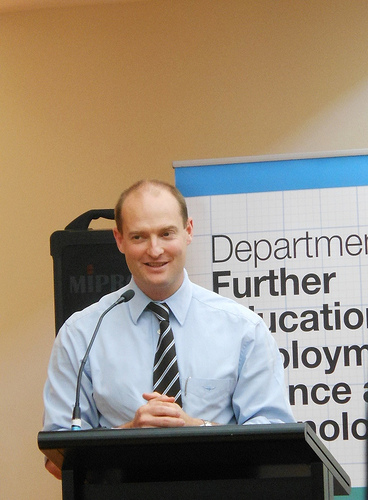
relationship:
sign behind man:
[169, 146, 363, 489] [26, 165, 304, 416]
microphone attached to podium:
[70, 289, 135, 432] [36, 420, 353, 497]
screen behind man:
[170, 152, 366, 497] [40, 177, 297, 432]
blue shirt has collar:
[42, 266, 297, 432] [123, 278, 198, 325]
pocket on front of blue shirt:
[182, 375, 236, 424] [42, 266, 297, 432]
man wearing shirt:
[40, 177, 297, 432] [36, 263, 294, 444]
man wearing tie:
[40, 177, 297, 432] [145, 291, 204, 416]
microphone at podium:
[68, 284, 140, 436] [7, 379, 352, 495]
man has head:
[40, 177, 297, 432] [112, 176, 194, 292]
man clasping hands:
[40, 177, 297, 432] [122, 390, 202, 427]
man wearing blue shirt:
[26, 165, 304, 416] [42, 266, 297, 432]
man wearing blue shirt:
[40, 177, 297, 432] [42, 266, 297, 432]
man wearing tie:
[40, 177, 297, 432] [147, 299, 182, 411]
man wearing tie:
[26, 165, 304, 416] [147, 299, 182, 411]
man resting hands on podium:
[40, 177, 297, 432] [36, 420, 353, 497]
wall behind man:
[38, 44, 277, 114] [101, 187, 209, 317]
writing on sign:
[208, 229, 366, 440] [189, 178, 365, 491]